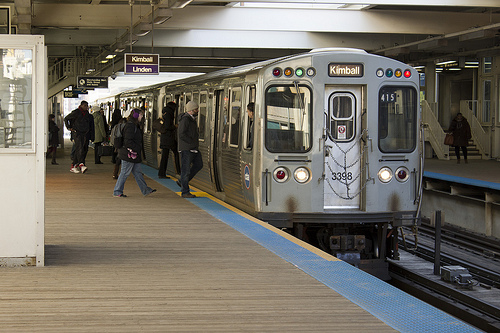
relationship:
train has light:
[103, 30, 436, 271] [278, 157, 321, 192]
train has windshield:
[103, 30, 436, 271] [256, 72, 326, 158]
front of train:
[291, 62, 406, 195] [103, 30, 436, 271]